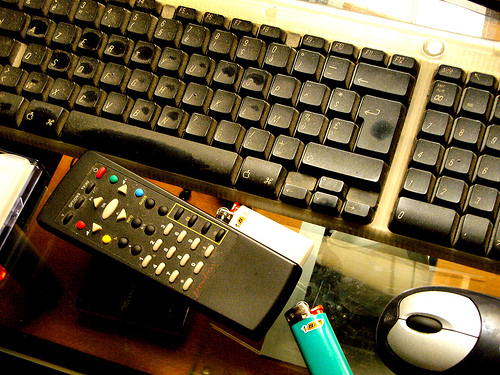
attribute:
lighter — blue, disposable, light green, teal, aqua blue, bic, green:
[281, 298, 360, 375]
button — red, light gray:
[308, 302, 325, 316]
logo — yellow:
[301, 316, 325, 333]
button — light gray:
[397, 287, 485, 340]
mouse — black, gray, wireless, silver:
[372, 278, 499, 375]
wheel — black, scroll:
[404, 311, 444, 334]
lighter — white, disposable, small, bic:
[213, 199, 318, 268]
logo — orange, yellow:
[235, 208, 252, 227]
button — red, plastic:
[228, 199, 242, 211]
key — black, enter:
[351, 87, 408, 163]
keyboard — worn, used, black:
[0, 0, 499, 278]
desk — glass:
[1, 1, 499, 375]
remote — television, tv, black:
[29, 146, 307, 351]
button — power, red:
[90, 163, 109, 186]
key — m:
[261, 99, 299, 136]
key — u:
[181, 51, 217, 89]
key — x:
[46, 74, 84, 112]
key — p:
[262, 72, 305, 108]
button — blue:
[133, 186, 146, 199]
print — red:
[190, 257, 220, 300]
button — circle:
[383, 195, 460, 252]